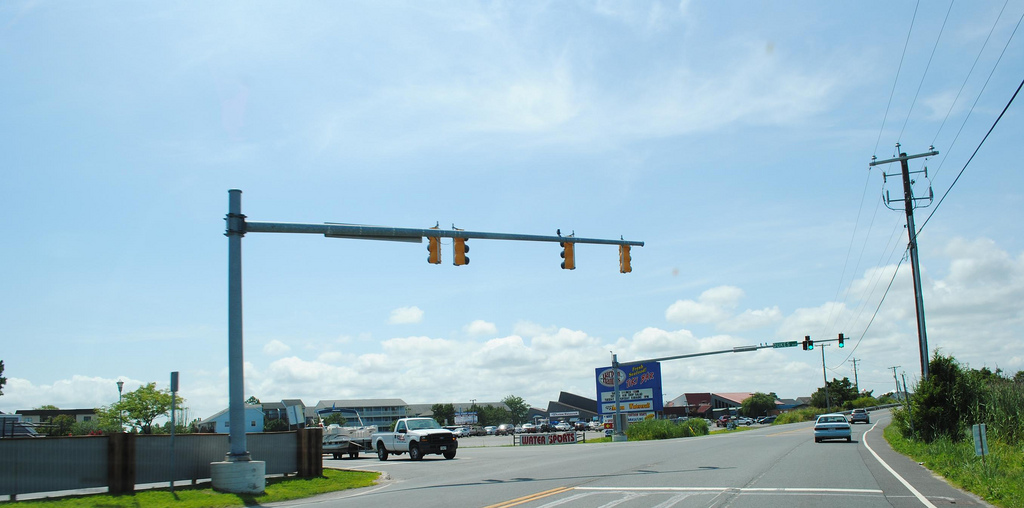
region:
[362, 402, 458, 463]
White truck stopped at a traffic signal.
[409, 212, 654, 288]
Four traffic signals hanging from the pole.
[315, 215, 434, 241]
Street sign on the bottom of the pole.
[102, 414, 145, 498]
Small trash can in front of the fence.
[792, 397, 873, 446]
Small white car driving down the road.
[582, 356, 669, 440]
Large blue and white sign in the ground.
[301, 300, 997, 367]
Bunch of clouds in the sky.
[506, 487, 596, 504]
Double solid yellow lines on the road.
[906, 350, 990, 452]
Large tree on the side of the road.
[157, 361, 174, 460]
Long street sign on the side of the road.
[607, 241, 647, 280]
light on the pole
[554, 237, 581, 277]
light on the pole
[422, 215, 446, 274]
light on the pole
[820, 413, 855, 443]
car on the road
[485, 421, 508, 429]
car on the road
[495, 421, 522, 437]
car on the road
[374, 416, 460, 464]
white truck stopped at the light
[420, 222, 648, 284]
yellow traffic lights hanging on a pole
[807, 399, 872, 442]
cars driving down the road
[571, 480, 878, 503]
white line painted across the street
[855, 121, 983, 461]
utility pole on the side of the road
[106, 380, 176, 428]
tree growing behind the fence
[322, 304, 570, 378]
white clouds gathered together in the sky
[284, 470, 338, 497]
green grass growing on the side of the road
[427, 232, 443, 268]
the hanging metal yellow traffic light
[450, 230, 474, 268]
the hanging metal yellow traffic light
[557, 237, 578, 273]
the hanging metal yellow traffic light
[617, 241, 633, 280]
the hanging metal yellow traffic light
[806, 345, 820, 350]
the bright green light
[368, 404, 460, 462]
the white truck driving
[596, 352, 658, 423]
the large blue sign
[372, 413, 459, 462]
white truck at the intersection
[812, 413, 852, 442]
white car on the road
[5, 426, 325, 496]
light brown fence with dark posts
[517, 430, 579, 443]
white sign with red letters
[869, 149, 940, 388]
tall metal power pole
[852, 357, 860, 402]
tall metal power pole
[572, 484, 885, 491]
white line painted on the road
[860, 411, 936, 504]
white line painted on the road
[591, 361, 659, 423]
large blue sign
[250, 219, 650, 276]
Stoplights hanging over road.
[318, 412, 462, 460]
White pickup truck towing a boat.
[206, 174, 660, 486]
a pole holding four traffic lights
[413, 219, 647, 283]
teh traffic lights are yellow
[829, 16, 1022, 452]
the wires pass over the plants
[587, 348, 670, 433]
a blue wall with advertising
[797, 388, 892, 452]
cars on the road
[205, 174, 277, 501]
the pole is gray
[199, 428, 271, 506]
the base of the pole is cement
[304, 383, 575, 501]
a car entering a road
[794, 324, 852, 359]
two traffic lights in green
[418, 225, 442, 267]
street signal on the pole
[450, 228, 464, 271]
street signal on the pole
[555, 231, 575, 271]
street signal on the pole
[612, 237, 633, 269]
street signal on the pole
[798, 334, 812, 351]
street signal on the pole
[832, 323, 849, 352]
street signal on the pole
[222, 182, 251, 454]
pole by the black street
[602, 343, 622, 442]
pole by the black street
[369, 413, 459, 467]
a white truck